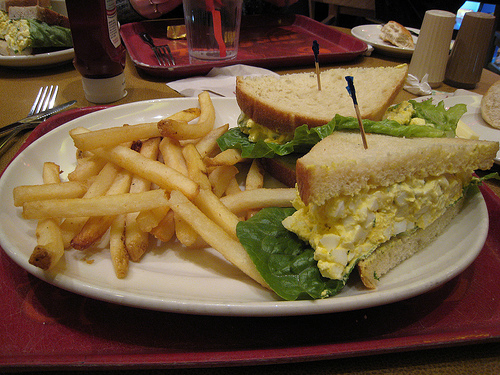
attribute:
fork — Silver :
[4, 81, 59, 166]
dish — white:
[3, 97, 491, 307]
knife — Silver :
[0, 83, 60, 152]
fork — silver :
[0, 74, 70, 113]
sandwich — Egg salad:
[296, 130, 498, 291]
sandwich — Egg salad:
[233, 64, 405, 129]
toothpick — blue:
[340, 72, 369, 114]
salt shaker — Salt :
[406, 6, 454, 89]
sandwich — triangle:
[222, 63, 458, 233]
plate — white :
[5, 89, 493, 313]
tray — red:
[1, 97, 498, 373]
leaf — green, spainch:
[238, 198, 361, 312]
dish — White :
[21, 85, 489, 315]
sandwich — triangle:
[283, 123, 498, 290]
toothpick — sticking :
[341, 72, 370, 149]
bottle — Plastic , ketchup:
[57, 4, 137, 102]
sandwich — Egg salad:
[232, 59, 499, 291]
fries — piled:
[28, 85, 307, 308]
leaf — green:
[235, 171, 497, 299]